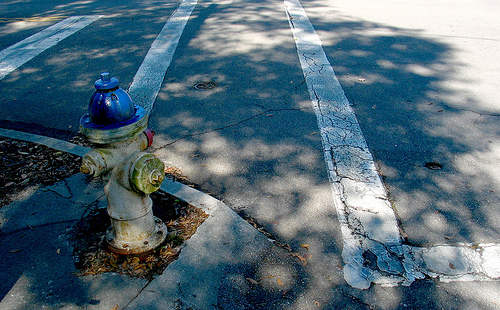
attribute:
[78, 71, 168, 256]
hydrant — old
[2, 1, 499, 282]
street — worn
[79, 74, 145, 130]
cap — blue, metal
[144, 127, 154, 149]
plug — red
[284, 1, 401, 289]
line — painted, white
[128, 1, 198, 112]
line — white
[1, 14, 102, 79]
line — white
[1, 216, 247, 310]
sidewalk — shaded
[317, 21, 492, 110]
shadow — trees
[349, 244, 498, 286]
line — white